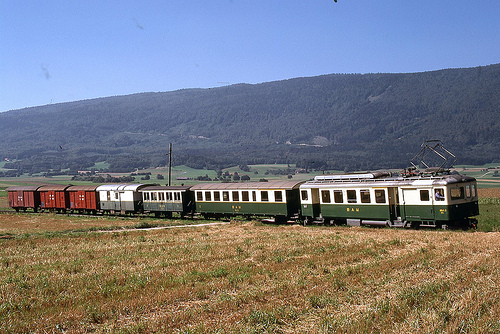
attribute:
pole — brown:
[165, 142, 173, 186]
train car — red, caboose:
[7, 185, 40, 213]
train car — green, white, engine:
[298, 168, 481, 232]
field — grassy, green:
[1, 211, 499, 334]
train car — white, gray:
[94, 180, 160, 216]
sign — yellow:
[232, 204, 243, 213]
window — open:
[346, 189, 358, 204]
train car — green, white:
[189, 181, 310, 218]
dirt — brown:
[6, 217, 91, 234]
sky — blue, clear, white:
[1, 0, 499, 112]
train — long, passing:
[7, 171, 480, 232]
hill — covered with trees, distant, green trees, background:
[0, 63, 499, 164]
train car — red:
[36, 184, 70, 214]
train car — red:
[67, 184, 99, 217]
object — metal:
[409, 139, 457, 179]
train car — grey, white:
[138, 185, 195, 213]